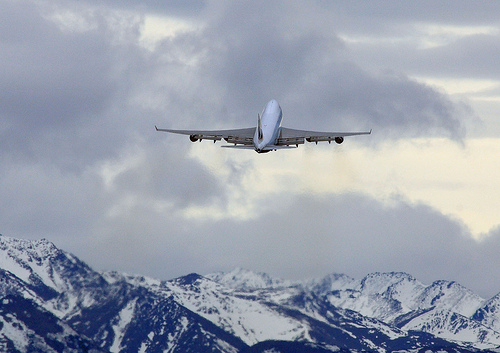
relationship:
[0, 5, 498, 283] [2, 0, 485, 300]
cloud in sky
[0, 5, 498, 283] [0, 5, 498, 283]
cloud in cloud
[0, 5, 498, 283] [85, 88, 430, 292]
cloud in sky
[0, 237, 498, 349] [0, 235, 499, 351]
mountain covered with snow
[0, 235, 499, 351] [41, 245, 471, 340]
snow over mountain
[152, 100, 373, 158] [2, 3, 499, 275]
plane is in sky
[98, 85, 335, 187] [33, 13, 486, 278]
plane in sky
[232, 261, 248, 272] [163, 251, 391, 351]
point of a mountain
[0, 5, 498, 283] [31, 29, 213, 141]
cloud in sky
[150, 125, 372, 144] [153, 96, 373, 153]
wings of a plane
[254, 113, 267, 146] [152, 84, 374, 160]
tail of plane